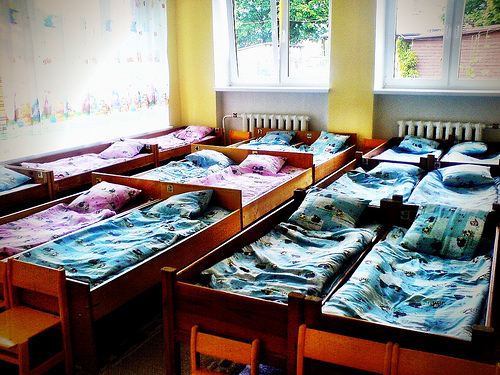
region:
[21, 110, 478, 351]
the beds are close together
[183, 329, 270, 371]
the stool is wooden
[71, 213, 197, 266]
the sheet is blue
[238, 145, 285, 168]
the pillowis pink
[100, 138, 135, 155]
the pillow is pink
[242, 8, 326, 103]
it is daylight outside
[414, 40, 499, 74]
bricks are on the wall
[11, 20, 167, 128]
drawings are on the wall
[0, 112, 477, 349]
the beds are 15 in total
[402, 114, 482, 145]
the air conditioner is mettalic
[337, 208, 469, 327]
blue sheets on bed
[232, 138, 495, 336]
six beds in a row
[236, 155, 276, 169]
pink pillow on the bed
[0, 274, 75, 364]
chair next to bed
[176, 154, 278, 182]
pink and blue sheets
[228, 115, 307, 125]
white radiators in back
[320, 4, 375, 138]
wall is yellow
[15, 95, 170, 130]
painted designs on the wall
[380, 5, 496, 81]
two windows in the back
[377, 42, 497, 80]
brick wall outside of room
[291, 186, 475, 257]
two blue pillows on bed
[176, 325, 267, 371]
chair in front of bear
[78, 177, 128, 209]
a pink pillow on bed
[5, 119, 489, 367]
a group of small bed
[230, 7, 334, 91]
windows above the the beds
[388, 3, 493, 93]
windows above the beds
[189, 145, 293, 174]
pink and blue pillows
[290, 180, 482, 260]
2 pillows next to each other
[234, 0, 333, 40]
trees outside the window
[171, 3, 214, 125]
yellow wall next to window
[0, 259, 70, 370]
wooden chair at end of bed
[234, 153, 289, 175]
pink pillow on bed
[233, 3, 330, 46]
trees outside window on left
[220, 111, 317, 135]
white radiator under window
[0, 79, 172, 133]
animals characters on wall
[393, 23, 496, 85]
brick building outside window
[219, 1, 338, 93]
window at left of picture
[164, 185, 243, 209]
wooden headboard on bed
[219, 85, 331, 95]
white window sill on left of picture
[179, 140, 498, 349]
beds with blue pillows and spreads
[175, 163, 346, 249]
Beds in a room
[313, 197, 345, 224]
A pillow on a bed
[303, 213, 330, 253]
A pillow and a mattress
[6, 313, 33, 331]
A wooden chair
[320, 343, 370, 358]
A wooden back rest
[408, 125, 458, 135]
Heating system on the wall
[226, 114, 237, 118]
Heating piping on the wall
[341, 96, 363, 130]
Yellow part of the wall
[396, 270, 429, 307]
A sunken mattress in the centre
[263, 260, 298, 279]
A ruffled up bed cover